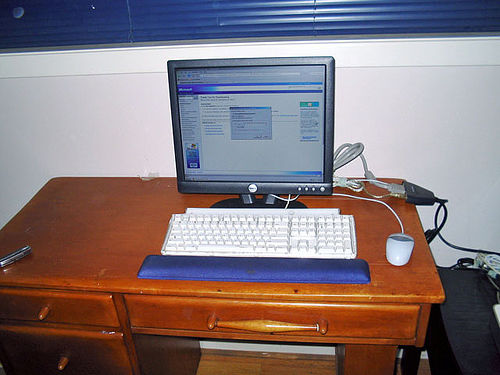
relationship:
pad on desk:
[133, 254, 370, 286] [2, 175, 448, 369]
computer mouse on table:
[377, 216, 459, 285] [2, 173, 445, 373]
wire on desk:
[269, 143, 498, 295] [2, 175, 448, 369]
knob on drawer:
[35, 308, 50, 319] [2, 289, 120, 328]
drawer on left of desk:
[2, 289, 120, 328] [2, 175, 448, 369]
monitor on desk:
[162, 54, 333, 195] [2, 175, 448, 369]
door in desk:
[1, 286, 128, 330] [2, 175, 448, 369]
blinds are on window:
[2, 1, 498, 43] [4, 0, 496, 47]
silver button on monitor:
[246, 183, 259, 193] [172, 59, 328, 184]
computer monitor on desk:
[162, 55, 338, 209] [2, 175, 448, 369]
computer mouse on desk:
[384, 232, 414, 267] [16, 196, 458, 331]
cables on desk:
[332, 142, 404, 201] [2, 175, 448, 369]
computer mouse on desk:
[384, 232, 414, 267] [35, 146, 442, 339]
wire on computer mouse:
[355, 169, 417, 216] [384, 232, 414, 267]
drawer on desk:
[2, 289, 120, 328] [8, 173, 142, 360]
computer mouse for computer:
[384, 232, 414, 267] [165, 56, 336, 208]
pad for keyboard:
[151, 249, 299, 294] [125, 213, 337, 270]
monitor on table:
[162, 54, 333, 195] [3, 177, 436, 342]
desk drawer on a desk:
[119, 295, 422, 342] [2, 175, 448, 369]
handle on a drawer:
[202, 313, 332, 338] [119, 288, 423, 350]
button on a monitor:
[318, 185, 327, 191] [162, 54, 333, 195]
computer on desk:
[160, 56, 357, 259] [2, 175, 448, 369]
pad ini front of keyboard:
[133, 254, 370, 286] [157, 205, 357, 261]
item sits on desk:
[2, 243, 37, 281] [11, 154, 474, 357]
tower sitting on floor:
[425, 262, 498, 373] [186, 345, 433, 374]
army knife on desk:
[0, 234, 35, 270] [2, 175, 448, 369]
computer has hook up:
[163, 56, 360, 260] [412, 184, 499, 248]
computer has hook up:
[163, 56, 360, 260] [339, 141, 404, 207]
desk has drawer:
[23, 158, 129, 359] [124, 289, 438, 346]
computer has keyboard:
[160, 56, 357, 259] [166, 189, 443, 267]